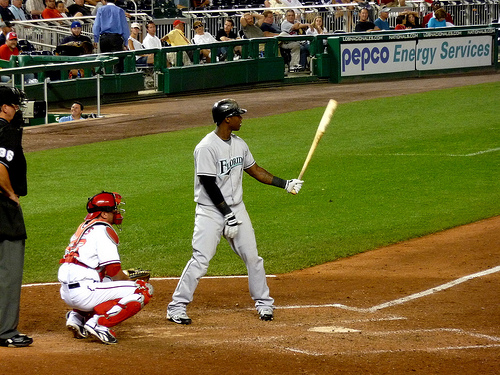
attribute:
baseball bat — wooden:
[293, 97, 343, 182]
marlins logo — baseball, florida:
[218, 156, 248, 181]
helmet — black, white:
[188, 80, 266, 137]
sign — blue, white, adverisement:
[338, 40, 490, 76]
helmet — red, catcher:
[87, 190, 124, 225]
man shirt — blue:
[75, 1, 137, 65]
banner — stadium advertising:
[340, 35, 492, 77]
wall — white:
[228, 103, 259, 160]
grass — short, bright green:
[34, 89, 495, 281]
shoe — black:
[0, 333, 34, 345]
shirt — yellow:
[165, 27, 191, 47]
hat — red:
[172, 19, 185, 24]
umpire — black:
[1, 80, 38, 352]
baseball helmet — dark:
[211, 99, 247, 124]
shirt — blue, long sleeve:
[89, 3, 129, 35]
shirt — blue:
[95, 5, 130, 40]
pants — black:
[99, 34, 121, 71]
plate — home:
[306, 323, 363, 334]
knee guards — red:
[96, 279, 153, 327]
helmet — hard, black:
[208, 97, 246, 119]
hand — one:
[270, 164, 310, 208]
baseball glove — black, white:
[221, 210, 241, 243]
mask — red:
[113, 192, 125, 232]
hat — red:
[6, 31, 20, 40]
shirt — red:
[0, 42, 25, 57]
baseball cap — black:
[212, 97, 246, 123]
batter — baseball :
[164, 94, 303, 328]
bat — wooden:
[289, 96, 337, 193]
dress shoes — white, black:
[2, 331, 34, 349]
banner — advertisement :
[333, 38, 499, 78]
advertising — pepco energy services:
[329, 28, 495, 83]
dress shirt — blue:
[93, 5, 128, 44]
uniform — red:
[54, 218, 152, 335]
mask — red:
[83, 192, 128, 221]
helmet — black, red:
[86, 189, 111, 214]